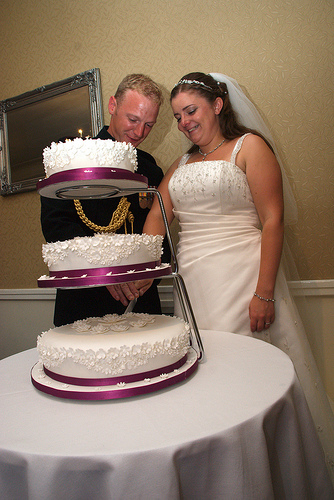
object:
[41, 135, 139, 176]
frosting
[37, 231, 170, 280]
frosting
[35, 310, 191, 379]
frosting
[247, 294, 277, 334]
hand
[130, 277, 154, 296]
hand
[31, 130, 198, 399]
cake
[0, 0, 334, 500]
wall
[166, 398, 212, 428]
table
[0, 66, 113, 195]
mirror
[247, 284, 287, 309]
bracelet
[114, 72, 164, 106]
man's hair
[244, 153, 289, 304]
arm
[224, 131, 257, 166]
strap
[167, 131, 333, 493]
dress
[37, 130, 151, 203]
tier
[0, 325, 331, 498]
linen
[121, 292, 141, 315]
knife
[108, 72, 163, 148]
head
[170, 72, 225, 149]
head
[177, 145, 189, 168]
strap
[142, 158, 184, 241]
arm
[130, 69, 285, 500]
lady